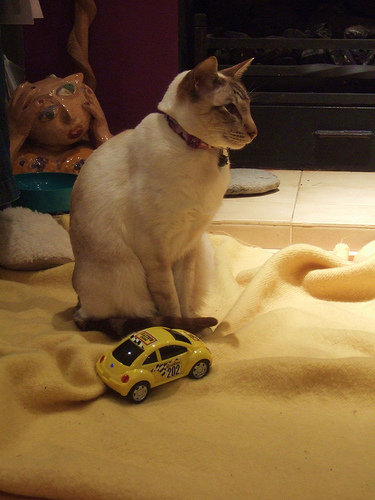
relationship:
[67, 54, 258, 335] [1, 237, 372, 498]
cat on blanket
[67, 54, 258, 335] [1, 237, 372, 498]
cat on surface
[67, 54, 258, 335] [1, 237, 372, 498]
cat on cushion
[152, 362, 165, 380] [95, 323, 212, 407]
graphic on vehicle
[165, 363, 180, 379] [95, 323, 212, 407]
numbering on vehicle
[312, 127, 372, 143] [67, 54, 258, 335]
handle behind cat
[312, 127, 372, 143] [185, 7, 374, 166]
handle on structure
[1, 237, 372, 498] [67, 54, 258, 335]
cushion behind cat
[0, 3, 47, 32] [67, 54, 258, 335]
paper behind cat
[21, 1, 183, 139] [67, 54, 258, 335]
wall behind cat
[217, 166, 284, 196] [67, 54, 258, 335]
stone behind cat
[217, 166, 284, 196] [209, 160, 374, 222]
stone on surface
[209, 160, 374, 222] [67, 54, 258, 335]
surface behind cat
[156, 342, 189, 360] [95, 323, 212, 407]
window on vehicle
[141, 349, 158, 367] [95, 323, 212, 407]
window on vehicle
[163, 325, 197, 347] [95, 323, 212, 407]
window on vehicle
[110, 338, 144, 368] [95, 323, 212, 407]
window on vehicle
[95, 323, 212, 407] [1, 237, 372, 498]
bug on blanket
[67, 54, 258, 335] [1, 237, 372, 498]
cat on bed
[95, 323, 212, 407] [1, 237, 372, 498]
car on bed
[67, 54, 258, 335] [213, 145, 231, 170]
cat has pendant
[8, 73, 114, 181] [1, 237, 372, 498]
vase near bed